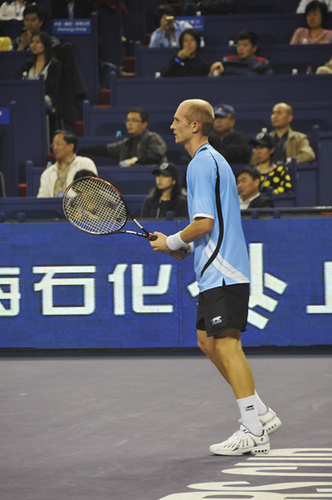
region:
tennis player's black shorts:
[191, 278, 257, 338]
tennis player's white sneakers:
[197, 404, 298, 459]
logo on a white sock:
[242, 401, 255, 415]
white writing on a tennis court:
[143, 434, 330, 498]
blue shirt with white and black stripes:
[178, 137, 255, 289]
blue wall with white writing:
[0, 219, 331, 355]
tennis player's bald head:
[174, 92, 215, 110]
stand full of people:
[0, 2, 331, 204]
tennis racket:
[60, 173, 164, 250]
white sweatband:
[161, 225, 190, 252]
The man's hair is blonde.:
[170, 100, 217, 145]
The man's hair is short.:
[169, 98, 214, 147]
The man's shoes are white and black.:
[205, 391, 282, 461]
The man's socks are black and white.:
[210, 394, 283, 458]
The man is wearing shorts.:
[196, 283, 252, 336]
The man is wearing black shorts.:
[192, 278, 255, 336]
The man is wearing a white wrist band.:
[164, 231, 190, 252]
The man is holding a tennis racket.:
[56, 177, 194, 260]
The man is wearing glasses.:
[122, 108, 146, 135]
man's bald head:
[170, 93, 220, 111]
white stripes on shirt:
[196, 244, 250, 284]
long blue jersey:
[174, 144, 259, 302]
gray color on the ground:
[58, 382, 159, 453]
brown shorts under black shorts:
[207, 322, 245, 348]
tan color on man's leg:
[216, 355, 256, 373]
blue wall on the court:
[32, 220, 179, 337]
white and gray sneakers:
[210, 425, 286, 464]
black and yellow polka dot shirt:
[254, 162, 298, 197]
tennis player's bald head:
[161, 91, 222, 118]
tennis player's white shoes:
[198, 390, 285, 455]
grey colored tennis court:
[0, 343, 331, 495]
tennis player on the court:
[145, 95, 290, 451]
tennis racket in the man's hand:
[56, 171, 177, 258]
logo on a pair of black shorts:
[208, 312, 226, 328]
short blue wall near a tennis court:
[1, 211, 331, 363]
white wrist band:
[163, 228, 186, 251]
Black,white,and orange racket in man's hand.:
[41, 160, 142, 236]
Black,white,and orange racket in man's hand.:
[241, 131, 285, 171]